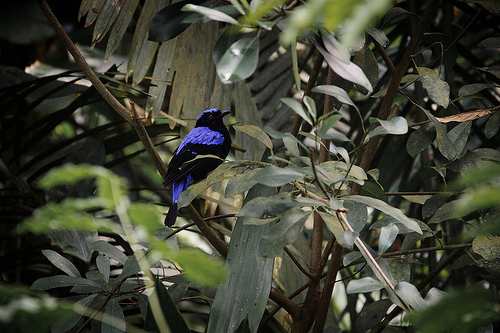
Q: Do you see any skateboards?
A: No, there are no skateboards.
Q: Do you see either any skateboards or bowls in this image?
A: No, there are no skateboards or bowls.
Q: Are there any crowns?
A: No, there are no crowns.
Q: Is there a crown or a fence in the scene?
A: No, there are no crowns or fences.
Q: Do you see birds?
A: Yes, there is a bird.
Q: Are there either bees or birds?
A: Yes, there is a bird.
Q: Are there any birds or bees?
A: Yes, there is a bird.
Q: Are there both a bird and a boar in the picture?
A: No, there is a bird but no boars.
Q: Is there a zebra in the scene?
A: No, there are no zebras.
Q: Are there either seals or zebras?
A: No, there are no zebras or seals.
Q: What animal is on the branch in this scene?
A: The bird is on the branch.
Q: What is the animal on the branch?
A: The animal is a bird.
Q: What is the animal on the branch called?
A: The animal is a bird.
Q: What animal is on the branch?
A: The animal is a bird.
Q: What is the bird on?
A: The bird is on the branch.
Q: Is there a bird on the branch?
A: Yes, there is a bird on the branch.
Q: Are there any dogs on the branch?
A: No, there is a bird on the branch.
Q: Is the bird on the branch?
A: Yes, the bird is on the branch.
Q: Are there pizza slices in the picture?
A: No, there are no pizza slices.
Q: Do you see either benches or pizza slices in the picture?
A: No, there are no pizza slices or benches.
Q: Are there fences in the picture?
A: No, there are no fences.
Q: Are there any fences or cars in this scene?
A: No, there are no fences or cars.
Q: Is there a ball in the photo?
A: No, there are no balls.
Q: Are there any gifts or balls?
A: No, there are no balls or gifts.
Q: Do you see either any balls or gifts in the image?
A: No, there are no balls or gifts.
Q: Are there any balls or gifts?
A: No, there are no balls or gifts.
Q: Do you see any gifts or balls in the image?
A: No, there are no balls or gifts.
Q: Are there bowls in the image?
A: No, there are no bowls.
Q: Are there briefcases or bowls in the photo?
A: No, there are no bowls or briefcases.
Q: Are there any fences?
A: No, there are no fences.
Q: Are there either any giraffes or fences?
A: No, there are no fences or giraffes.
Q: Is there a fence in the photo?
A: No, there are no fences.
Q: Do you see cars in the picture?
A: No, there are no cars.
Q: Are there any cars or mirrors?
A: No, there are no cars or mirrors.